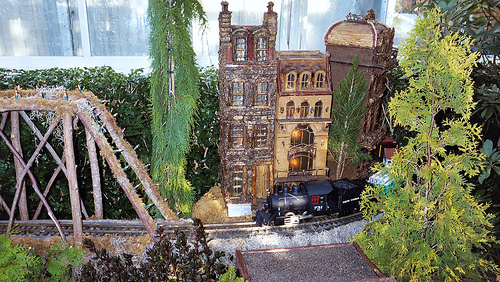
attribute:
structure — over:
[2, 85, 183, 250]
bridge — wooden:
[0, 83, 175, 246]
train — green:
[244, 172, 398, 230]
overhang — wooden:
[1, 80, 183, 245]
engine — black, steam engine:
[255, 169, 395, 234]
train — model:
[251, 176, 376, 223]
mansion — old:
[217, 0, 400, 210]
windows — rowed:
[282, 65, 331, 92]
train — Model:
[225, 160, 447, 252]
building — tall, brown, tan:
[275, 42, 329, 179]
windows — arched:
[274, 61, 329, 96]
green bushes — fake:
[0, 65, 218, 218]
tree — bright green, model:
[353, 5, 499, 280]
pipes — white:
[369, 160, 399, 184]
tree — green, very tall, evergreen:
[147, 0, 209, 217]